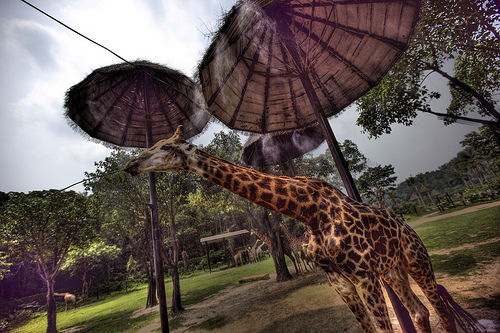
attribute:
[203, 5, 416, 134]
umbrella — open, natural, brown, small, close, fiber, wooden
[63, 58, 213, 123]
umbrella — open, natural, brown, small, close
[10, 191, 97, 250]
leaves — green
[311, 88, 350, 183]
pole — brown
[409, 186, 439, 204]
huts — pointy, brown, small, far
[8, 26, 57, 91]
cloud — white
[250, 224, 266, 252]
giraffe — standing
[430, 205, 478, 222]
dirt — brown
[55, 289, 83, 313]
giraffe — far, standing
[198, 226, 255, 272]
structure — open, far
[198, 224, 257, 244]
roof — brown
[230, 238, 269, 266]
giraffes — far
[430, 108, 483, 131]
limb — long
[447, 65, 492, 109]
limb — big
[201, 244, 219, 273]
pole — black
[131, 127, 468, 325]
giraffe — leaning, brown, orange, tall, close, standing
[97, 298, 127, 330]
grass — green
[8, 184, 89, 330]
tree — small, green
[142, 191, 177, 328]
pole — brown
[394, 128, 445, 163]
sky — gray, dark, blue, cloudy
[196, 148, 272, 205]
spots — brown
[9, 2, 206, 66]
clouds — white